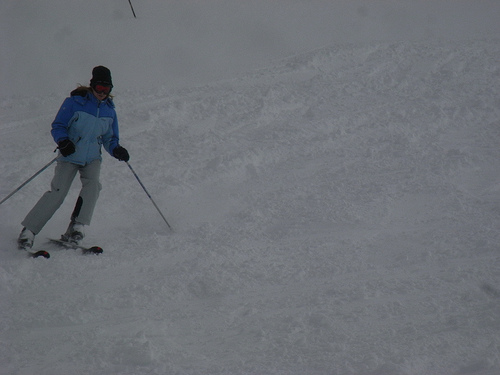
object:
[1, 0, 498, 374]
snow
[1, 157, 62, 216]
pole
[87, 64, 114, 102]
head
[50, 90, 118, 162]
coat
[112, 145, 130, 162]
glove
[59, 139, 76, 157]
glove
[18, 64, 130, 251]
woman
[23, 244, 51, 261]
ski equipment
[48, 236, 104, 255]
ski equipment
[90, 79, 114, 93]
goggles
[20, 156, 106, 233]
pants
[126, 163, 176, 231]
poles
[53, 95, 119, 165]
jacket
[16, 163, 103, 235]
snow pants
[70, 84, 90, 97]
hood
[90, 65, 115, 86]
hat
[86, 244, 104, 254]
top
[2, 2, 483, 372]
photo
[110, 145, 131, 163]
hands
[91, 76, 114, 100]
face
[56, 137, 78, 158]
hand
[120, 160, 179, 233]
gear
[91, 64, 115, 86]
beanie